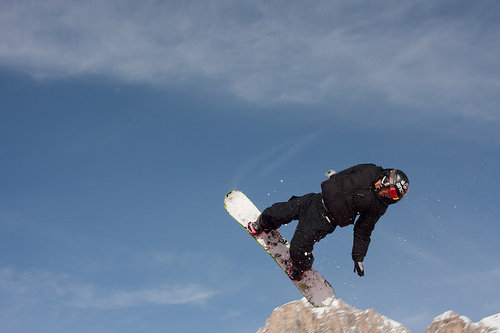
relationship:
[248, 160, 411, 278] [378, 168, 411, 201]
man has helmet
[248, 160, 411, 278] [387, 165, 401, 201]
man has goggles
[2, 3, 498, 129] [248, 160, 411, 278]
cloud over man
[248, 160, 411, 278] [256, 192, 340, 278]
man has pants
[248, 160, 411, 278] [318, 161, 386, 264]
man has jacket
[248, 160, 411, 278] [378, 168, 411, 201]
man wearing helmet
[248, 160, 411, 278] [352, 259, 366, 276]
man wearing glove